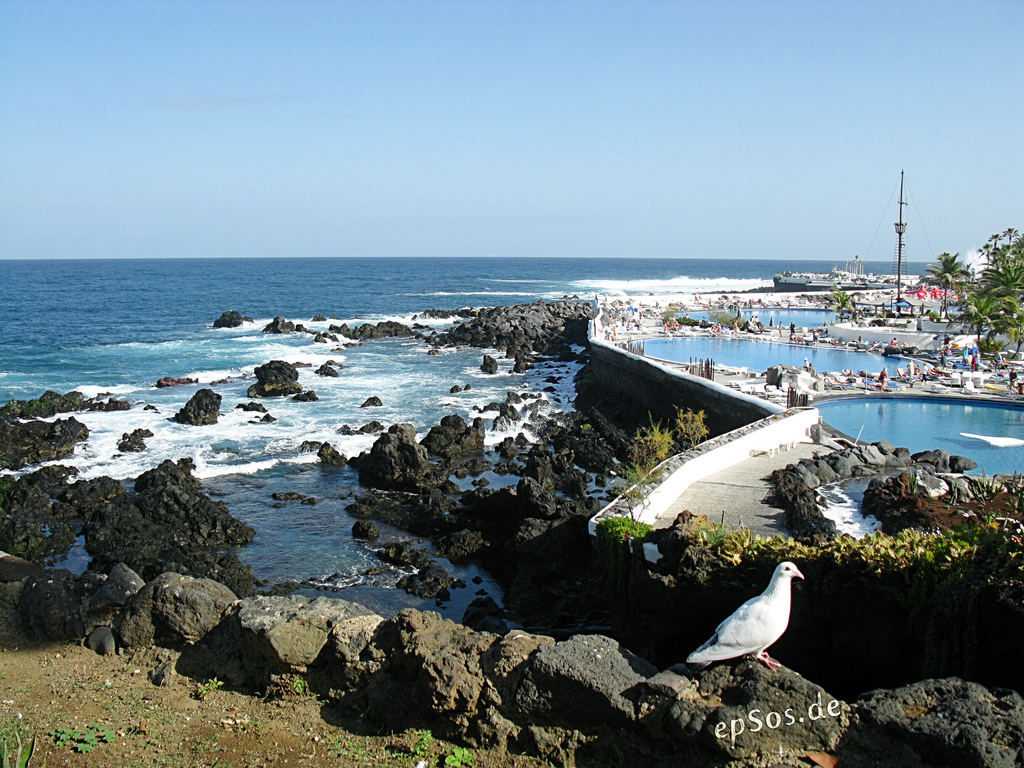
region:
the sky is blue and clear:
[7, 4, 985, 251]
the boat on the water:
[752, 262, 926, 289]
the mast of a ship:
[875, 152, 926, 293]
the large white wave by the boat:
[537, 262, 772, 292]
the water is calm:
[0, 259, 617, 585]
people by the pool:
[793, 357, 996, 399]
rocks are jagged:
[369, 406, 507, 476]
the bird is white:
[670, 551, 803, 672]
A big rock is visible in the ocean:
[245, 358, 318, 403]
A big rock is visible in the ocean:
[213, 306, 253, 333]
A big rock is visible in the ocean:
[266, 315, 299, 336]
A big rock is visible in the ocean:
[361, 389, 385, 412]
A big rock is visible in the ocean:
[359, 417, 439, 495]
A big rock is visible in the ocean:
[424, 410, 491, 474]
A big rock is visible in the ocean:
[210, 309, 253, 338]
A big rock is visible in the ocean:
[2, 413, 89, 468]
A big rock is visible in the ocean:
[324, 319, 420, 346]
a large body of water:
[4, 244, 949, 385]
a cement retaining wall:
[574, 296, 828, 556]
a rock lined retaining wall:
[4, 564, 1019, 765]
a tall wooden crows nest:
[892, 166, 909, 300]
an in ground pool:
[800, 384, 1023, 489]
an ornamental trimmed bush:
[662, 406, 708, 457]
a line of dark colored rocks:
[18, 555, 1018, 767]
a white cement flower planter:
[586, 410, 805, 532]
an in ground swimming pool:
[625, 327, 924, 376]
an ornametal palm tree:
[925, 246, 967, 319]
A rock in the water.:
[350, 513, 385, 542]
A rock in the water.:
[405, 563, 448, 605]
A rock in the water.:
[103, 567, 227, 650]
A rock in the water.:
[89, 615, 141, 658]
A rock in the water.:
[173, 390, 216, 417]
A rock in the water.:
[240, 362, 304, 404]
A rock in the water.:
[285, 389, 327, 406]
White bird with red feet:
[683, 551, 808, 681]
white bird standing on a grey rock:
[681, 546, 856, 746]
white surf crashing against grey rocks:
[136, 374, 250, 457]